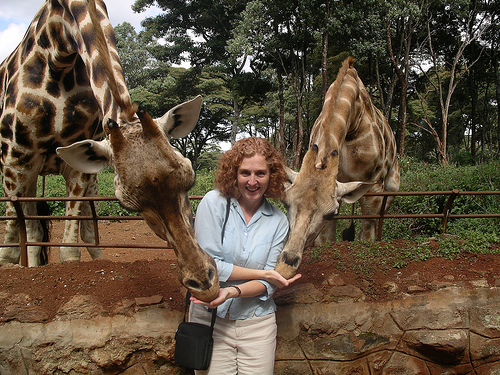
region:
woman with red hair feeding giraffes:
[175, 138, 298, 374]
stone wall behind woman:
[2, 265, 492, 373]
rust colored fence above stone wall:
[0, 194, 497, 256]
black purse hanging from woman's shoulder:
[172, 187, 232, 367]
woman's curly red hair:
[217, 138, 287, 199]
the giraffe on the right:
[282, 63, 397, 253]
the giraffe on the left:
[5, 1, 220, 298]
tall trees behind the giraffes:
[112, 3, 498, 165]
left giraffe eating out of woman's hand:
[55, 94, 230, 306]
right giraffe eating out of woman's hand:
[270, 158, 375, 288]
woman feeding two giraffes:
[183, 142, 295, 373]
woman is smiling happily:
[217, 135, 285, 205]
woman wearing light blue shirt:
[196, 139, 288, 317]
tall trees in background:
[116, 4, 493, 158]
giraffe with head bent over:
[57, 1, 217, 302]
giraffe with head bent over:
[280, 63, 397, 285]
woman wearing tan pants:
[190, 137, 288, 374]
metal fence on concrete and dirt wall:
[2, 192, 154, 369]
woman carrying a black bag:
[173, 309, 218, 373]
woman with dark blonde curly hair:
[218, 134, 284, 209]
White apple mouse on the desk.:
[186, 364, 200, 371]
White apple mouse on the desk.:
[238, 363, 278, 371]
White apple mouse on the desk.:
[306, 196, 360, 226]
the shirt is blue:
[201, 194, 286, 319]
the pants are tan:
[187, 306, 272, 374]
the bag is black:
[178, 291, 223, 369]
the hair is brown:
[221, 137, 291, 202]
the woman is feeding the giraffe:
[177, 126, 298, 373]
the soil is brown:
[77, 263, 148, 301]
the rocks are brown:
[323, 302, 483, 373]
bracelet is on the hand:
[230, 279, 251, 303]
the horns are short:
[92, 101, 167, 151]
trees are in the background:
[161, 18, 496, 65]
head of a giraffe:
[38, 62, 252, 292]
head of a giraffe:
[260, 142, 381, 294]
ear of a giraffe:
[31, 128, 125, 210]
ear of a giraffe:
[140, 76, 246, 153]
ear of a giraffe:
[262, 145, 322, 200]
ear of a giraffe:
[343, 167, 425, 209]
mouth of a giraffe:
[183, 256, 243, 306]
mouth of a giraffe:
[250, 241, 316, 281]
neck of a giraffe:
[73, 22, 130, 125]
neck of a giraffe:
[303, 87, 388, 142]